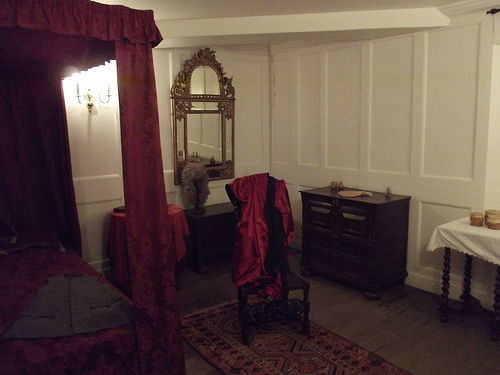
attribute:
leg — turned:
[492, 265, 498, 335]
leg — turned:
[438, 247, 452, 324]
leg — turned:
[460, 251, 475, 318]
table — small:
[427, 208, 495, 343]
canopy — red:
[9, 14, 170, 95]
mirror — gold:
[167, 43, 237, 189]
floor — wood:
[378, 304, 436, 355]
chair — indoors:
[215, 172, 350, 359]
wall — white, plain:
[265, 2, 499, 314]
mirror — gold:
[168, 42, 247, 197]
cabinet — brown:
[180, 198, 237, 272]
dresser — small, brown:
[249, 161, 430, 309]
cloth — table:
[111, 209, 188, 296]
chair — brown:
[220, 168, 320, 349]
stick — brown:
[438, 248, 451, 322]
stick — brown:
[490, 266, 499, 342]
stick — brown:
[460, 253, 472, 315]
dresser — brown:
[297, 190, 404, 296]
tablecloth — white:
[424, 207, 484, 249]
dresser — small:
[297, 180, 421, 312]